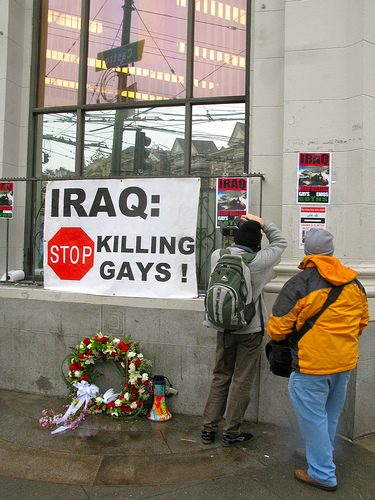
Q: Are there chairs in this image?
A: No, there are no chairs.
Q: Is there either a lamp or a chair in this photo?
A: No, there are no chairs or lamps.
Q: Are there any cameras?
A: Yes, there is a camera.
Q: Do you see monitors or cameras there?
A: Yes, there is a camera.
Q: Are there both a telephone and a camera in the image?
A: No, there is a camera but no phones.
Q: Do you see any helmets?
A: No, there are no helmets.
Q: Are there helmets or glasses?
A: No, there are no helmets or glasses.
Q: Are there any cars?
A: No, there are no cars.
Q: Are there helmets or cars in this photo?
A: No, there are no cars or helmets.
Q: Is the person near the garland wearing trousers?
A: Yes, the person is wearing trousers.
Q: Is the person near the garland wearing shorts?
A: No, the person is wearing trousers.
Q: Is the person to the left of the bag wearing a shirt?
A: Yes, the person is wearing a shirt.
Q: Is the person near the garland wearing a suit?
A: No, the person is wearing a shirt.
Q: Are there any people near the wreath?
A: Yes, there is a person near the wreath.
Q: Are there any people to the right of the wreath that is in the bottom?
A: Yes, there is a person to the right of the wreath.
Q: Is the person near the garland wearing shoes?
A: Yes, the person is wearing shoes.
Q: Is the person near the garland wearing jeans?
A: No, the person is wearing shoes.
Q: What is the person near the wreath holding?
A: The person is holding the camera.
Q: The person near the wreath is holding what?
A: The person is holding the camera.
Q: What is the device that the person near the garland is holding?
A: The device is a camera.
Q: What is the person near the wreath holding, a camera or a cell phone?
A: The person is holding a camera.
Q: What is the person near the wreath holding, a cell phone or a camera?
A: The person is holding a camera.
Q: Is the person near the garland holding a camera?
A: Yes, the person is holding a camera.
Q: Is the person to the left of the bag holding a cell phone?
A: No, the person is holding a camera.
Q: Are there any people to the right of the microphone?
A: Yes, there is a person to the right of the microphone.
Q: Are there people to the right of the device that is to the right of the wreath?
A: Yes, there is a person to the right of the microphone.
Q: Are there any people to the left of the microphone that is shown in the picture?
A: No, the person is to the right of the microphone.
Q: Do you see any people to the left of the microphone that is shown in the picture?
A: No, the person is to the right of the microphone.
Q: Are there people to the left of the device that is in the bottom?
A: No, the person is to the right of the microphone.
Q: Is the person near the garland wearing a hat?
A: Yes, the person is wearing a hat.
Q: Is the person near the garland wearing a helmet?
A: No, the person is wearing a hat.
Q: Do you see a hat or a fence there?
A: Yes, there is a hat.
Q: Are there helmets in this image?
A: No, there are no helmets.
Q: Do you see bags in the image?
A: Yes, there is a bag.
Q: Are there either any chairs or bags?
A: Yes, there is a bag.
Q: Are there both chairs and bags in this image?
A: No, there is a bag but no chairs.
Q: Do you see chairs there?
A: No, there are no chairs.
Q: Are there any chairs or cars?
A: No, there are no chairs or cars.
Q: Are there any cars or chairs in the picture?
A: No, there are no chairs or cars.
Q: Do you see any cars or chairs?
A: No, there are no chairs or cars.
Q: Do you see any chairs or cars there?
A: No, there are no chairs or cars.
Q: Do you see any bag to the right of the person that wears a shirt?
A: Yes, there is a bag to the right of the person.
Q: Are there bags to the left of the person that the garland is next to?
A: No, the bag is to the right of the person.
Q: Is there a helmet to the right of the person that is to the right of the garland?
A: No, there is a bag to the right of the person.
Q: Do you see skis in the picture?
A: No, there are no skis.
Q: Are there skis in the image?
A: No, there are no skis.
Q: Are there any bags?
A: Yes, there is a bag.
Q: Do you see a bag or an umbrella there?
A: Yes, there is a bag.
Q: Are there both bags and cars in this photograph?
A: No, there is a bag but no cars.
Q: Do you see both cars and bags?
A: No, there is a bag but no cars.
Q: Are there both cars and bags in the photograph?
A: No, there is a bag but no cars.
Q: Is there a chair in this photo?
A: No, there are no chairs.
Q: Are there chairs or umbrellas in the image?
A: No, there are no chairs or umbrellas.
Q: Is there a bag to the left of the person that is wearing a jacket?
A: Yes, there is a bag to the left of the person.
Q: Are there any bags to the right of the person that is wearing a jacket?
A: No, the bag is to the left of the person.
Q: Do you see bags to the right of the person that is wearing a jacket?
A: No, the bag is to the left of the person.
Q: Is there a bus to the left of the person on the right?
A: No, there is a bag to the left of the person.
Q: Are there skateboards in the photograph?
A: No, there are no skateboards.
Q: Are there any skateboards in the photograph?
A: No, there are no skateboards.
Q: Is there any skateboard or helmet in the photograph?
A: No, there are no skateboards or helmets.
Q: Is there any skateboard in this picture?
A: No, there are no skateboards.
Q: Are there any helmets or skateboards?
A: No, there are no skateboards or helmets.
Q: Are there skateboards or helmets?
A: No, there are no skateboards or helmets.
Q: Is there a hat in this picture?
A: Yes, there is a hat.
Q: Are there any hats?
A: Yes, there is a hat.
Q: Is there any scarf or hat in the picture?
A: Yes, there is a hat.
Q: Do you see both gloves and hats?
A: No, there is a hat but no gloves.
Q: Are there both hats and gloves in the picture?
A: No, there is a hat but no gloves.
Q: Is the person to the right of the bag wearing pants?
A: Yes, the person is wearing pants.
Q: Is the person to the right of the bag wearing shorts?
A: No, the person is wearing pants.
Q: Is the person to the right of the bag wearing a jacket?
A: Yes, the person is wearing a jacket.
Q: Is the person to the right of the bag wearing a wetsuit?
A: No, the person is wearing a jacket.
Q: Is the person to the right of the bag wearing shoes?
A: Yes, the person is wearing shoes.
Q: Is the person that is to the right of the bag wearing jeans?
A: No, the person is wearing shoes.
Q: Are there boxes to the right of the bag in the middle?
A: No, there is a person to the right of the bag.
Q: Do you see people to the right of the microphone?
A: Yes, there is a person to the right of the microphone.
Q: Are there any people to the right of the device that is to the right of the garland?
A: Yes, there is a person to the right of the microphone.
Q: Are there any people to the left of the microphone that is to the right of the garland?
A: No, the person is to the right of the microphone.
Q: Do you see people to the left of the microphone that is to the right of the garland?
A: No, the person is to the right of the microphone.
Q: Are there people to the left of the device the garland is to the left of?
A: No, the person is to the right of the microphone.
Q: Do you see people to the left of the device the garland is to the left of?
A: No, the person is to the right of the microphone.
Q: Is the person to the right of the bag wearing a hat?
A: Yes, the person is wearing a hat.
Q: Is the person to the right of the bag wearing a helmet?
A: No, the person is wearing a hat.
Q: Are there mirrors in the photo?
A: No, there are no mirrors.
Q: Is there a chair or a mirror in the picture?
A: No, there are no mirrors or chairs.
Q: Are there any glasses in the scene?
A: No, there are no glasses.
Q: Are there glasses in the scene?
A: No, there are no glasses.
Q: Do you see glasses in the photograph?
A: No, there are no glasses.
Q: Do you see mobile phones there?
A: No, there are no mobile phones.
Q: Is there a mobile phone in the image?
A: No, there are no cell phones.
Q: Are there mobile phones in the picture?
A: No, there are no mobile phones.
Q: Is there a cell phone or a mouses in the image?
A: No, there are no cell phones or computer mousess.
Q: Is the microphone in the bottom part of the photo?
A: Yes, the microphone is in the bottom of the image.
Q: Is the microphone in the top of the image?
A: No, the microphone is in the bottom of the image.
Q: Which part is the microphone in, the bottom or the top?
A: The microphone is in the bottom of the image.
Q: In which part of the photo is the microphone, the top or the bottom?
A: The microphone is in the bottom of the image.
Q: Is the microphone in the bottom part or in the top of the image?
A: The microphone is in the bottom of the image.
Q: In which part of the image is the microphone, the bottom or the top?
A: The microphone is in the bottom of the image.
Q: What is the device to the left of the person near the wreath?
A: The device is a microphone.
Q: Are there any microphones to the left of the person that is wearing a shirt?
A: Yes, there is a microphone to the left of the person.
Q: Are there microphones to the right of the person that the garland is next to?
A: No, the microphone is to the left of the person.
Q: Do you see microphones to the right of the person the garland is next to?
A: No, the microphone is to the left of the person.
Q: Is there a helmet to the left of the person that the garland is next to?
A: No, there is a microphone to the left of the person.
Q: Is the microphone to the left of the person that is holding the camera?
A: Yes, the microphone is to the left of the person.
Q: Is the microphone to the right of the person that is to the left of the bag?
A: No, the microphone is to the left of the person.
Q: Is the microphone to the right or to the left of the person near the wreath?
A: The microphone is to the left of the person.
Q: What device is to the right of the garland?
A: The device is a microphone.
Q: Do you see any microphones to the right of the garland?
A: Yes, there is a microphone to the right of the garland.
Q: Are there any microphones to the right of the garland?
A: Yes, there is a microphone to the right of the garland.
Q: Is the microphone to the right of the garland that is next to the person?
A: Yes, the microphone is to the right of the wreath.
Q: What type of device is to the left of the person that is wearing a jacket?
A: The device is a microphone.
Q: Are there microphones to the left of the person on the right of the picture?
A: Yes, there is a microphone to the left of the person.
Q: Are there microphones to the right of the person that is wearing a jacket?
A: No, the microphone is to the left of the person.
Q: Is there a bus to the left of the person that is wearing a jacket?
A: No, there is a microphone to the left of the person.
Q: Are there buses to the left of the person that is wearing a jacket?
A: No, there is a microphone to the left of the person.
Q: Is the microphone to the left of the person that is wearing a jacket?
A: Yes, the microphone is to the left of the person.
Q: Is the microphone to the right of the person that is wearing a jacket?
A: No, the microphone is to the left of the person.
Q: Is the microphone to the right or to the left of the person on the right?
A: The microphone is to the left of the person.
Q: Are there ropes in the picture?
A: No, there are no ropes.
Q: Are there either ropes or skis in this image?
A: No, there are no ropes or skis.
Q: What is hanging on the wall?
A: The paper is hanging on the wall.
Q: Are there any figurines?
A: No, there are no figurines.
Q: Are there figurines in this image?
A: No, there are no figurines.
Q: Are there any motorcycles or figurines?
A: No, there are no figurines or motorcycles.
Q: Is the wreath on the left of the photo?
A: Yes, the wreath is on the left of the image.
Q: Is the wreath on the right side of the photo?
A: No, the wreath is on the left of the image.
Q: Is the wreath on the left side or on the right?
A: The wreath is on the left of the image.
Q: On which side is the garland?
A: The garland is on the left of the image.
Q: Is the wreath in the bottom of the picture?
A: Yes, the wreath is in the bottom of the image.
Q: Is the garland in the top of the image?
A: No, the garland is in the bottom of the image.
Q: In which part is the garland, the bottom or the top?
A: The garland is in the bottom of the image.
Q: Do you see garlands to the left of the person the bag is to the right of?
A: Yes, there is a garland to the left of the person.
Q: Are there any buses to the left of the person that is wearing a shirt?
A: No, there is a garland to the left of the person.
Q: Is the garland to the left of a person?
A: Yes, the garland is to the left of a person.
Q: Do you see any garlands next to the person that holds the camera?
A: Yes, there is a garland next to the person.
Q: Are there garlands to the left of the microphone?
A: Yes, there is a garland to the left of the microphone.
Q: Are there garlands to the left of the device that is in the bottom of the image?
A: Yes, there is a garland to the left of the microphone.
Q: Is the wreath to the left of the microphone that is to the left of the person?
A: Yes, the wreath is to the left of the microphone.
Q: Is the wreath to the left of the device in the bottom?
A: Yes, the wreath is to the left of the microphone.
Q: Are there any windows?
A: Yes, there is a window.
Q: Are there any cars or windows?
A: Yes, there is a window.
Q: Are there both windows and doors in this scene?
A: No, there is a window but no doors.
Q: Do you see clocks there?
A: No, there are no clocks.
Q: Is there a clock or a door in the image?
A: No, there are no clocks or doors.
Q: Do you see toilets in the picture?
A: No, there are no toilets.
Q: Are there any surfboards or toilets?
A: No, there are no toilets or surfboards.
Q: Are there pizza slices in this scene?
A: No, there are no pizza slices.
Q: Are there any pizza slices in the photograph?
A: No, there are no pizza slices.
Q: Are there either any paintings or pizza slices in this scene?
A: No, there are no pizza slices or paintings.